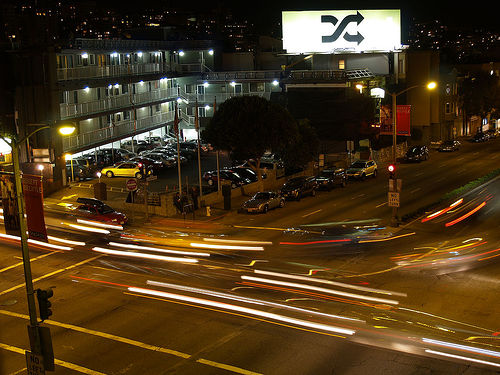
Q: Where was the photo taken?
A: It was taken at the street.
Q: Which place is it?
A: It is a street.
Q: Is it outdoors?
A: Yes, it is outdoors.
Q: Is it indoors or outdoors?
A: It is outdoors.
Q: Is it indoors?
A: No, it is outdoors.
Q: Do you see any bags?
A: No, there are no bags.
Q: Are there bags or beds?
A: No, there are no bags or beds.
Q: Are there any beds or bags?
A: No, there are no bags or beds.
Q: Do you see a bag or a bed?
A: No, there are no bags or beds.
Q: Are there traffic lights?
A: Yes, there is a traffic light.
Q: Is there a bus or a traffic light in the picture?
A: Yes, there is a traffic light.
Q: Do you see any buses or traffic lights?
A: Yes, there is a traffic light.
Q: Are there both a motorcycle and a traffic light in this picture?
A: No, there is a traffic light but no motorcycles.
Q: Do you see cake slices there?
A: No, there are no cake slices.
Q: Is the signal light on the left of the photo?
A: Yes, the signal light is on the left of the image.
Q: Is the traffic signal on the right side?
A: No, the traffic signal is on the left of the image.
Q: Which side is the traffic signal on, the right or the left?
A: The traffic signal is on the left of the image.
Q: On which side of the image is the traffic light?
A: The traffic light is on the left of the image.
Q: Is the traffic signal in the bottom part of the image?
A: Yes, the traffic signal is in the bottom of the image.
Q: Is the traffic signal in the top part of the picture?
A: No, the traffic signal is in the bottom of the image.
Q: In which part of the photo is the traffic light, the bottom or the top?
A: The traffic light is in the bottom of the image.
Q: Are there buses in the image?
A: No, there are no buses.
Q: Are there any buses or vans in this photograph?
A: No, there are no buses or vans.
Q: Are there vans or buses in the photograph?
A: No, there are no buses or vans.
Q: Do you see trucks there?
A: No, there are no trucks.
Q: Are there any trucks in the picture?
A: No, there are no trucks.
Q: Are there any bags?
A: No, there are no bags.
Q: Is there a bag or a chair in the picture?
A: No, there are no bags or chairs.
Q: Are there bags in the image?
A: No, there are no bags.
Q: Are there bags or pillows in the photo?
A: No, there are no bags or pillows.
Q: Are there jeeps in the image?
A: No, there are no jeeps.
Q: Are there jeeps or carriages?
A: No, there are no jeeps or carriages.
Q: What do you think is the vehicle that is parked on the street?
A: The vehicle is a car.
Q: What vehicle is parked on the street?
A: The vehicle is a car.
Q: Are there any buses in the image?
A: No, there are no buses.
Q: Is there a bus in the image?
A: No, there are no buses.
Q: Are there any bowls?
A: No, there are no bowls.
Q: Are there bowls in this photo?
A: No, there are no bowls.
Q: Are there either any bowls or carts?
A: No, there are no bowls or carts.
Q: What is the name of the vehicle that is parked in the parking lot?
A: The vehicle is a car.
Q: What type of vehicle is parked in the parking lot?
A: The vehicle is a car.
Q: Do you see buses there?
A: No, there are no buses.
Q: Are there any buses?
A: No, there are no buses.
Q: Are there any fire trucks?
A: No, there are no fire trucks.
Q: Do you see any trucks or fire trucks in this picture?
A: No, there are no fire trucks or trucks.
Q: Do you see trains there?
A: No, there are no trains.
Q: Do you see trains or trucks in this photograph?
A: No, there are no trains or trucks.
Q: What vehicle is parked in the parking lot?
A: The vehicle is a car.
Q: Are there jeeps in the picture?
A: No, there are no jeeps.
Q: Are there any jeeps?
A: No, there are no jeeps.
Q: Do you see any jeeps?
A: No, there are no jeeps.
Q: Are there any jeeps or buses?
A: No, there are no jeeps or buses.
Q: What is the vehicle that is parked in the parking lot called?
A: The vehicle is a car.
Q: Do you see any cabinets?
A: No, there are no cabinets.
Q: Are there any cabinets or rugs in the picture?
A: No, there are no cabinets or rugs.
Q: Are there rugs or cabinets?
A: No, there are no cabinets or rugs.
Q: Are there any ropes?
A: No, there are no ropes.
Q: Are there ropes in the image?
A: No, there are no ropes.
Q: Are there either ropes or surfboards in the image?
A: No, there are no ropes or surfboards.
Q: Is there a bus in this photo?
A: No, there are no buses.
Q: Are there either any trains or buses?
A: No, there are no buses or trains.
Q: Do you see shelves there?
A: No, there are no shelves.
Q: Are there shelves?
A: No, there are no shelves.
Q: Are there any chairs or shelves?
A: No, there are no shelves or chairs.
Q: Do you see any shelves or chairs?
A: No, there are no shelves or chairs.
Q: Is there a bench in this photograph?
A: No, there are no benches.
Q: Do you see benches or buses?
A: No, there are no benches or buses.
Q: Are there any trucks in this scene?
A: No, there are no trucks.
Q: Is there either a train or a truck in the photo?
A: No, there are no trucks or trains.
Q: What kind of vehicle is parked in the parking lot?
A: The vehicle is a car.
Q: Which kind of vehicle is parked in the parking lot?
A: The vehicle is a car.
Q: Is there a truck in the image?
A: No, there are no trucks.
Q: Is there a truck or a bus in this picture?
A: No, there are no trucks or buses.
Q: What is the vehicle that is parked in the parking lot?
A: The vehicle is a car.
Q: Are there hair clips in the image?
A: No, there are no hair clips.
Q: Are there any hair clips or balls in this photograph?
A: No, there are no hair clips or balls.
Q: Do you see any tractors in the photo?
A: No, there are no tractors.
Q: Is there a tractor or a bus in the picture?
A: No, there are no tractors or buses.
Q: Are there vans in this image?
A: No, there are no vans.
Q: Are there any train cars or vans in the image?
A: No, there are no vans or train cars.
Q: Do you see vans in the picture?
A: No, there are no vans.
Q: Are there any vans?
A: No, there are no vans.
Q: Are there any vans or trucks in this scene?
A: No, there are no vans or trucks.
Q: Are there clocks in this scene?
A: No, there are no clocks.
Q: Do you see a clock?
A: No, there are no clocks.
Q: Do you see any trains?
A: No, there are no trains.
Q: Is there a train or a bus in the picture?
A: No, there are no trains or buses.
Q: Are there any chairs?
A: No, there are no chairs.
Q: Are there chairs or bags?
A: No, there are no chairs or bags.